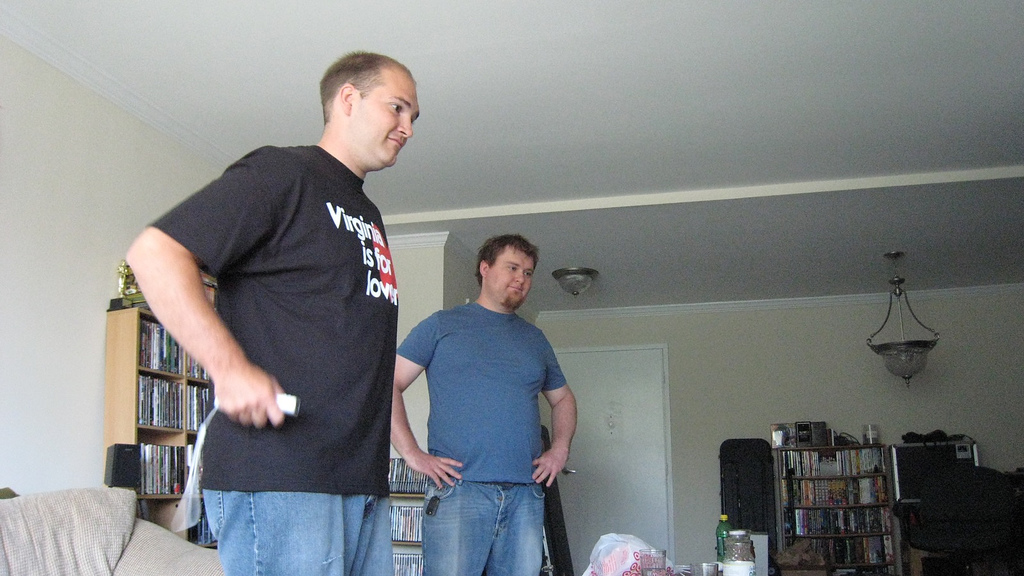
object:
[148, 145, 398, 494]
t shirt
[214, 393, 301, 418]
wii remote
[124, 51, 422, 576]
man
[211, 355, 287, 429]
hand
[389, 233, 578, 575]
man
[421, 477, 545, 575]
jeans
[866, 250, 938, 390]
light fixture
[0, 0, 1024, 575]
living room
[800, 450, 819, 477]
book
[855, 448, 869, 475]
book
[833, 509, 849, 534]
book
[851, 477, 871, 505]
book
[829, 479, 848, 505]
book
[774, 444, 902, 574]
book shelf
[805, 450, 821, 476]
book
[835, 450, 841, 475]
movie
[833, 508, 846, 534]
movie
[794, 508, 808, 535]
movie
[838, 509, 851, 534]
movie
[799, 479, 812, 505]
movie